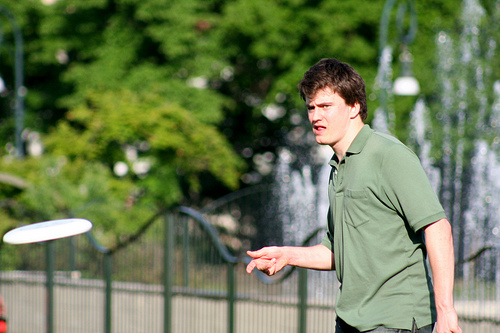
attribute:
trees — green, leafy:
[59, 9, 270, 211]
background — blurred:
[94, 30, 201, 112]